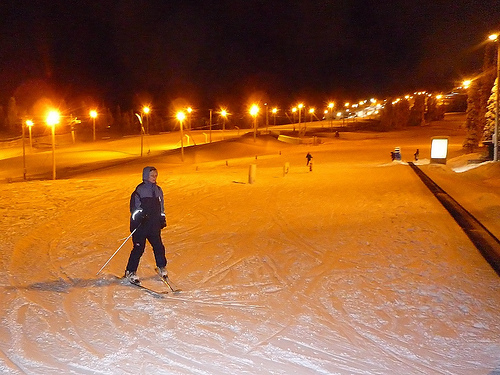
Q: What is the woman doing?
A: Skiing.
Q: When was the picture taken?
A: At night.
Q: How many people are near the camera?
A: 1.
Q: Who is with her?
A: No one.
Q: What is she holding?
A: A stick.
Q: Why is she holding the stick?
A: For support.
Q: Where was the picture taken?
A: At a ski resort.